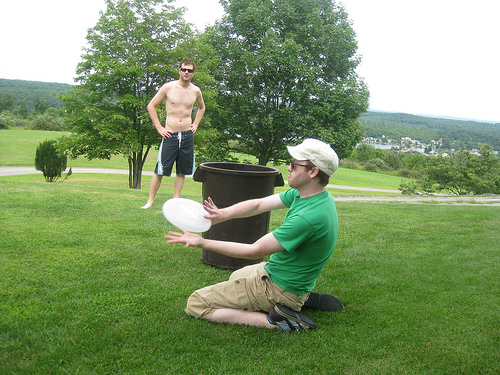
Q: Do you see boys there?
A: No, there are no boys.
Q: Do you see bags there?
A: No, there are no bags.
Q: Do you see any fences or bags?
A: No, there are no bags or fences.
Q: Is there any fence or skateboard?
A: No, there are no fences or skateboards.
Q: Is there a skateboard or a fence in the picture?
A: No, there are no fences or skateboards.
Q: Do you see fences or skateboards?
A: No, there are no fences or skateboards.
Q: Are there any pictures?
A: No, there are no pictures.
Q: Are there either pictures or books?
A: No, there are no pictures or books.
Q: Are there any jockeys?
A: No, there are no jockeys.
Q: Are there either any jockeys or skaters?
A: No, there are no jockeys or skaters.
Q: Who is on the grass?
A: The man is on the grass.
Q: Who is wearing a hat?
A: The man is wearing a hat.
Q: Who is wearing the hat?
A: The man is wearing a hat.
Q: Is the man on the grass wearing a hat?
A: Yes, the man is wearing a hat.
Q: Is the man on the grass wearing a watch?
A: No, the man is wearing a hat.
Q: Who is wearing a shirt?
A: The man is wearing a shirt.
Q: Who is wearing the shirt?
A: The man is wearing a shirt.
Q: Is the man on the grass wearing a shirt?
A: Yes, the man is wearing a shirt.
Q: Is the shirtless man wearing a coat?
A: No, the man is wearing a shirt.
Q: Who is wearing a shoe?
A: The man is wearing a shoe.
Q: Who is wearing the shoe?
A: The man is wearing a shoe.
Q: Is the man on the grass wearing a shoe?
A: Yes, the man is wearing a shoe.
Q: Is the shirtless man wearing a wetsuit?
A: No, the man is wearing a shoe.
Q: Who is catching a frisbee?
A: The man is catching a frisbee.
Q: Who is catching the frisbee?
A: The man is catching a frisbee.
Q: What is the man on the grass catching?
A: The man is catching a frisbee.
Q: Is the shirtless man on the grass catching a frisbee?
A: Yes, the man is catching a frisbee.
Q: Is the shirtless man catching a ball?
A: No, the man is catching a frisbee.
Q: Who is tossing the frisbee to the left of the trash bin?
A: The man is tossing the frisbee.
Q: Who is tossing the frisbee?
A: The man is tossing the frisbee.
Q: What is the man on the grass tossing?
A: The man is tossing the frisbee.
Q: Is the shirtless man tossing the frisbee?
A: Yes, the man is tossing the frisbee.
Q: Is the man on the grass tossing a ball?
A: No, the man is tossing the frisbee.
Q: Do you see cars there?
A: No, there are no cars.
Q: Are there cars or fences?
A: No, there are no cars or fences.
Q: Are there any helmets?
A: No, there are no helmets.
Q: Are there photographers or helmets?
A: No, there are no helmets or photographers.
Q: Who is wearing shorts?
A: The man is wearing shorts.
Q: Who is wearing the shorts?
A: The man is wearing shorts.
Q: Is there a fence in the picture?
A: No, there are no fences.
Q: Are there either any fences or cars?
A: No, there are no fences or cars.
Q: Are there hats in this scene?
A: Yes, there is a hat.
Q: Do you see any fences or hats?
A: Yes, there is a hat.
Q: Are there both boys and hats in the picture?
A: No, there is a hat but no boys.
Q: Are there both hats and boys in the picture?
A: No, there is a hat but no boys.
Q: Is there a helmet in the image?
A: No, there are no helmets.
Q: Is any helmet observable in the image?
A: No, there are no helmets.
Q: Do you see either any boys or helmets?
A: No, there are no helmets or boys.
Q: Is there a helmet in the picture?
A: No, there are no helmets.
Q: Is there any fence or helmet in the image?
A: No, there are no helmets or fences.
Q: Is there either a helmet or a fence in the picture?
A: No, there are no helmets or fences.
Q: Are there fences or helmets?
A: No, there are no helmets or fences.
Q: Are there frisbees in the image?
A: Yes, there is a frisbee.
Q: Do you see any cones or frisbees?
A: Yes, there is a frisbee.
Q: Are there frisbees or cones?
A: Yes, there is a frisbee.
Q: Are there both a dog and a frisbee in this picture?
A: No, there is a frisbee but no dogs.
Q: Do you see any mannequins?
A: No, there are no mannequins.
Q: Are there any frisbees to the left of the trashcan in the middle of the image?
A: Yes, there is a frisbee to the left of the trashcan.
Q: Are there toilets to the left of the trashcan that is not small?
A: No, there is a frisbee to the left of the trash bin.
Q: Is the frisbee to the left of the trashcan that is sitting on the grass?
A: Yes, the frisbee is to the left of the trash can.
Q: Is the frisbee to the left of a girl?
A: No, the frisbee is to the left of the trash can.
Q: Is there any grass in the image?
A: Yes, there is grass.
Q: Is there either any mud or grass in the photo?
A: Yes, there is grass.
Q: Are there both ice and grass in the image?
A: No, there is grass but no ice.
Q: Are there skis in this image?
A: No, there are no skis.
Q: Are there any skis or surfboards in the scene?
A: No, there are no skis or surfboards.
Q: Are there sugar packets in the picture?
A: No, there are no sugar packets.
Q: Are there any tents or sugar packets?
A: No, there are no sugar packets or tents.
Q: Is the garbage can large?
A: Yes, the garbage can is large.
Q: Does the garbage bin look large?
A: Yes, the garbage bin is large.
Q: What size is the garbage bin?
A: The garbage bin is large.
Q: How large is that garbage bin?
A: The garbage bin is large.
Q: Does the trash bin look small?
A: No, the trash bin is large.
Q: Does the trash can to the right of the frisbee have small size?
A: No, the garbage bin is large.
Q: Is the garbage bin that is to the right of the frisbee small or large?
A: The garbage can is large.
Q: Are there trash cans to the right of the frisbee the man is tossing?
A: Yes, there is a trash can to the right of the frisbee.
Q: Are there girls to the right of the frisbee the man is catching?
A: No, there is a trash can to the right of the frisbee.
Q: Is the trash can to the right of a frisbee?
A: Yes, the trash can is to the right of a frisbee.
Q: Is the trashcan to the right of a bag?
A: No, the trashcan is to the right of a frisbee.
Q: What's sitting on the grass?
A: The garbage can is sitting on the grass.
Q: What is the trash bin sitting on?
A: The trash bin is sitting on the grass.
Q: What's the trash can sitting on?
A: The trash bin is sitting on the grass.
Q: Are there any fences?
A: No, there are no fences.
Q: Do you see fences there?
A: No, there are no fences.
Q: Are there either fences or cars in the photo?
A: No, there are no fences or cars.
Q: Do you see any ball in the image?
A: No, there are no balls.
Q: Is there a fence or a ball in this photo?
A: No, there are no balls or fences.